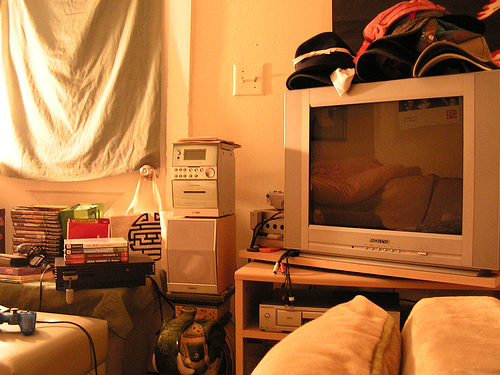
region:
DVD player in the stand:
[235, 280, 407, 347]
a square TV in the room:
[268, 58, 498, 276]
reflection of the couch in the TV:
[295, 103, 483, 253]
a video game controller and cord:
[0, 300, 96, 337]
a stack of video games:
[5, 195, 85, 273]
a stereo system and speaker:
[160, 121, 249, 329]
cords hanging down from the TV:
[265, 237, 311, 317]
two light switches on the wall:
[221, 58, 274, 95]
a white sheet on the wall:
[5, 1, 160, 191]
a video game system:
[48, 245, 160, 295]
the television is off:
[280, 93, 486, 233]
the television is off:
[237, 20, 454, 223]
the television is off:
[193, 41, 498, 296]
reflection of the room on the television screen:
[300, 94, 476, 250]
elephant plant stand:
[147, 286, 240, 373]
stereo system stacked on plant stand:
[155, 129, 235, 371]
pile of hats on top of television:
[270, 1, 495, 113]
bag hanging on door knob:
[105, 162, 175, 267]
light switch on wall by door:
[222, 52, 272, 106]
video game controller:
[0, 304, 44, 340]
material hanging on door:
[5, 0, 167, 188]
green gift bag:
[57, 199, 103, 237]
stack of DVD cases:
[6, 198, 64, 264]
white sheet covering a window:
[0, 0, 183, 190]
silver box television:
[287, 86, 499, 283]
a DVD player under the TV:
[252, 276, 427, 353]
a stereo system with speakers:
[165, 122, 231, 314]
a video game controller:
[0, 298, 49, 338]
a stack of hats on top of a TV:
[272, 2, 498, 99]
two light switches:
[227, 60, 276, 99]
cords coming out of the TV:
[263, 237, 308, 322]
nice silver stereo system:
[162, 121, 262, 219]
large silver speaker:
[151, 213, 240, 310]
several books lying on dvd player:
[62, 219, 130, 273]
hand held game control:
[0, 306, 60, 343]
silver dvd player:
[247, 297, 414, 341]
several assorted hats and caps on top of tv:
[290, 1, 496, 93]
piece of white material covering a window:
[15, 0, 197, 198]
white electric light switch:
[217, 47, 282, 113]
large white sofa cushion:
[235, 289, 428, 374]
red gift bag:
[52, 195, 124, 265]